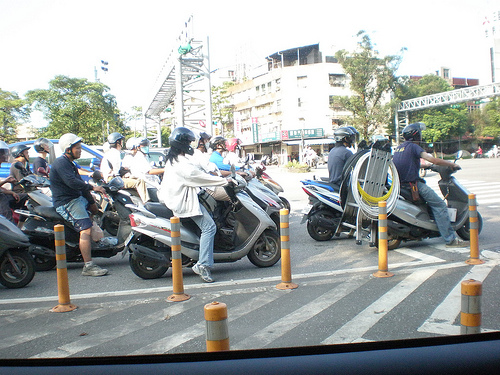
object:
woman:
[149, 136, 209, 258]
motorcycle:
[134, 174, 295, 280]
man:
[395, 120, 456, 242]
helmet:
[396, 121, 438, 141]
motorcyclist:
[312, 113, 371, 238]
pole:
[164, 206, 187, 301]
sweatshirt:
[41, 160, 96, 196]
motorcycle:
[361, 173, 482, 230]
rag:
[178, 36, 202, 60]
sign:
[277, 114, 343, 154]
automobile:
[2, 124, 117, 189]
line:
[272, 282, 359, 330]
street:
[235, 179, 477, 285]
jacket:
[164, 161, 226, 234]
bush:
[418, 108, 448, 142]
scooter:
[33, 193, 156, 267]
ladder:
[353, 146, 401, 229]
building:
[224, 69, 384, 169]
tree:
[33, 79, 129, 146]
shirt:
[392, 153, 419, 170]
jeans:
[412, 188, 466, 246]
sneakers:
[185, 261, 215, 282]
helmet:
[225, 135, 249, 157]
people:
[47, 117, 111, 203]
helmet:
[52, 131, 84, 149]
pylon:
[274, 207, 301, 288]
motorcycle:
[312, 128, 482, 249]